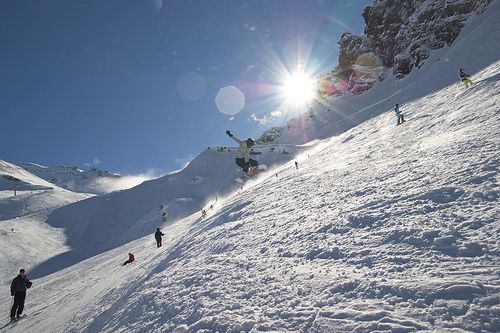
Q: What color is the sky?
A: Blue.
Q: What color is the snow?
A: White.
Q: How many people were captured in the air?
A: One.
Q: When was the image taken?
A: During the day.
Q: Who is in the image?
A: Skiers and snowboarders.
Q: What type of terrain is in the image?
A: Mountain.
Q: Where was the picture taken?
A: Ski resort.